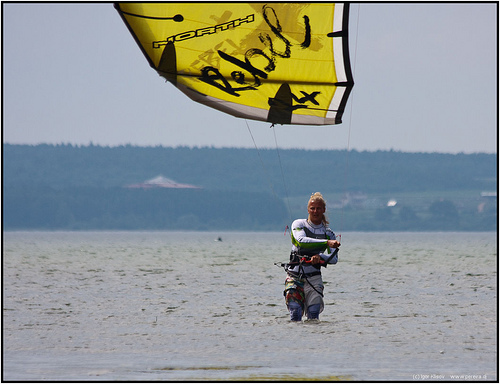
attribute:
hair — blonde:
[307, 191, 331, 231]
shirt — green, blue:
[290, 216, 340, 276]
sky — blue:
[4, 4, 481, 179]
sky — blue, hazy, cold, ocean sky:
[5, 2, 484, 164]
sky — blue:
[0, 0, 474, 151]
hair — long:
[305, 187, 330, 234]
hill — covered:
[4, 134, 484, 228]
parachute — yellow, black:
[95, 2, 364, 130]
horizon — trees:
[1, 127, 483, 165]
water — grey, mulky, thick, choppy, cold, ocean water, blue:
[4, 220, 480, 381]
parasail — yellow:
[106, 1, 364, 131]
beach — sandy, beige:
[0, 228, 499, 382]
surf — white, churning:
[126, 172, 195, 190]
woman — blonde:
[281, 183, 351, 325]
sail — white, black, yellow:
[107, 6, 372, 122]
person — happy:
[272, 186, 351, 321]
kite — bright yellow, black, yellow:
[106, 6, 367, 127]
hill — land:
[9, 183, 282, 232]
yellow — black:
[118, 6, 373, 130]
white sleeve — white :
[287, 224, 326, 250]